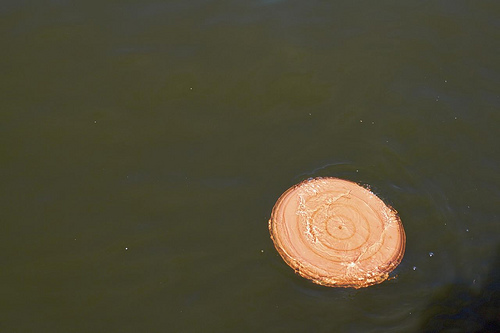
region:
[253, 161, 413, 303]
red Frisbee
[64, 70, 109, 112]
dark greenish brown water in river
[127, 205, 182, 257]
dark greenish brown water in river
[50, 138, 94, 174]
dark greenish brown water in river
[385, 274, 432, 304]
dark greenish brown water in river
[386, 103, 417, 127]
dark greenish brown water in river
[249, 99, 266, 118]
dark greenish brown water in river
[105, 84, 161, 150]
dark greenish brown water in river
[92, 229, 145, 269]
dark greenish brown water in river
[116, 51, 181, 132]
dark greenish brown water in river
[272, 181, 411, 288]
the wood is in the water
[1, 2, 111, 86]
the part of the water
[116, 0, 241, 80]
the part of the water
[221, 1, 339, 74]
the part of the water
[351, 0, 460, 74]
the part of the water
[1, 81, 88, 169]
the part of the water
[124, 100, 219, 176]
the part of the water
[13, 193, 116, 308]
the part of the water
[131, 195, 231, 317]
the part of the water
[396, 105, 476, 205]
the part of the water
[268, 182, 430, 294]
disc in the water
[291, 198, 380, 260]
disc is cracked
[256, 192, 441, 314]
round shape to disc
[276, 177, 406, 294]
disc is orange colored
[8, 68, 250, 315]
water surrounds disc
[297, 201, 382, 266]
spiral lines in the disc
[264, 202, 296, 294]
edges are thick on the side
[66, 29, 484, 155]
background is dark and green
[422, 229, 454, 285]
specks of white in the dark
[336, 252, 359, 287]
white particles on the disc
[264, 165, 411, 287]
Frisbee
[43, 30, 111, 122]
dark green water in river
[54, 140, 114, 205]
dark green water in river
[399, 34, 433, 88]
dark green water in river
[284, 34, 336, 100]
dark green water in river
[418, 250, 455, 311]
dark green water in river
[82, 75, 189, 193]
dark green water in river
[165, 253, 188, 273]
dark green water in river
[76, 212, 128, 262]
dark green water in river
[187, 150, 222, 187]
dark green water in river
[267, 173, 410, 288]
wood disc floating on top of the water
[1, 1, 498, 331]
water under wood disc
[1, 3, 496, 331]
water is green in color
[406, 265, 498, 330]
dark shadow visible on the surface of the water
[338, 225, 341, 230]
small dot in the center of the wood disc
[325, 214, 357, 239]
small circle surrounding dot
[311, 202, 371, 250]
circle surrounding circle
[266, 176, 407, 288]
wooden disc is wet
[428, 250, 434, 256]
white specks visible in the water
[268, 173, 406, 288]
wooden disc is flat